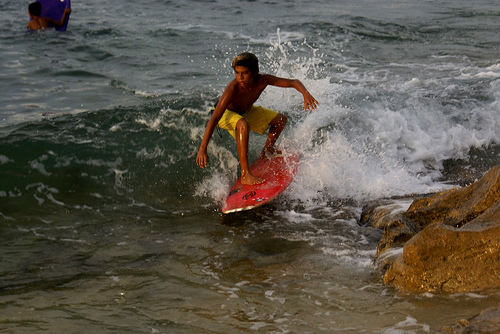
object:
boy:
[192, 51, 318, 185]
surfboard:
[219, 148, 297, 213]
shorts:
[217, 103, 282, 138]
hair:
[229, 51, 263, 74]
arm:
[200, 86, 237, 150]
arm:
[265, 75, 307, 92]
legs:
[220, 108, 248, 171]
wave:
[0, 65, 500, 231]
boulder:
[358, 154, 500, 294]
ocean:
[0, 0, 499, 333]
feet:
[238, 175, 265, 187]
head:
[229, 51, 259, 88]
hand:
[193, 150, 208, 167]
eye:
[242, 70, 251, 77]